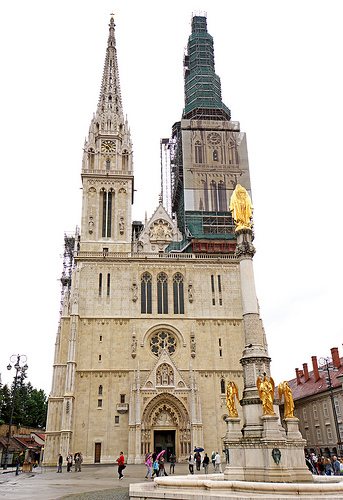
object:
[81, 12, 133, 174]
spire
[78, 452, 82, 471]
person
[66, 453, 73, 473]
person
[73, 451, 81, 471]
person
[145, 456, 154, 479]
person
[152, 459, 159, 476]
person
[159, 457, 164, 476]
person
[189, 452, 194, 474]
person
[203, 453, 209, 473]
person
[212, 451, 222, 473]
person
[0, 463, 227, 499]
court yard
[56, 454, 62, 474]
people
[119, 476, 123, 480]
foot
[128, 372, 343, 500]
fountain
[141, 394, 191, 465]
door way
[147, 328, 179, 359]
circular window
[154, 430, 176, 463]
doors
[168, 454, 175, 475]
person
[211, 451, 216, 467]
person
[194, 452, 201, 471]
person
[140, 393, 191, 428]
design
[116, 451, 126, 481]
man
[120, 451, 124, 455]
head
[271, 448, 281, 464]
head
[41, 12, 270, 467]
boulding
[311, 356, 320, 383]
chimney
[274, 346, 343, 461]
building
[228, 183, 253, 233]
statue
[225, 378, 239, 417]
statue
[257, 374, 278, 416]
statue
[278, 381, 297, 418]
statue